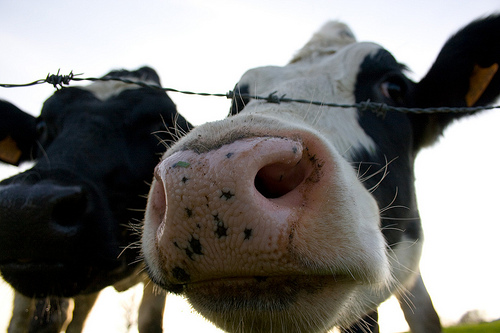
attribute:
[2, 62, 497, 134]
wire — barbed, metal, fence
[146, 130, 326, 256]
nostrils — dirty, white, pink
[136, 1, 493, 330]
cow — black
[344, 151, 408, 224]
whiskers — short, white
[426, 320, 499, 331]
grass — green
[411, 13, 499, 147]
ear — black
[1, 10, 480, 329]
cows — big, looking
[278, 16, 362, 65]
hump — white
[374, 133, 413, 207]
fur — black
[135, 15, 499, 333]
head — large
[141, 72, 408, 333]
face — black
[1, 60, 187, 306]
cow — black, looking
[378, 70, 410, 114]
eye — large, black, white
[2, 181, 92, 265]
nose — black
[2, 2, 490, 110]
sky — clear